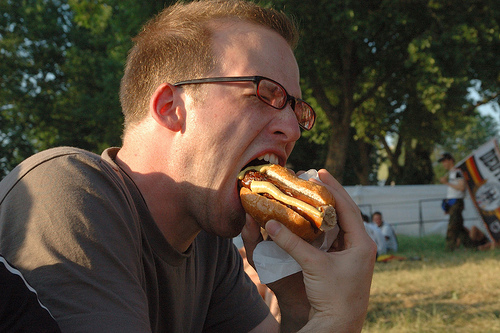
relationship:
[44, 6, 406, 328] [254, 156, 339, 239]
man eating hot dog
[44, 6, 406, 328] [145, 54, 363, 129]
man wearing eyeglasses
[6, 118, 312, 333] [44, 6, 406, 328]
shirt on man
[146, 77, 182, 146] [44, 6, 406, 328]
ear of man